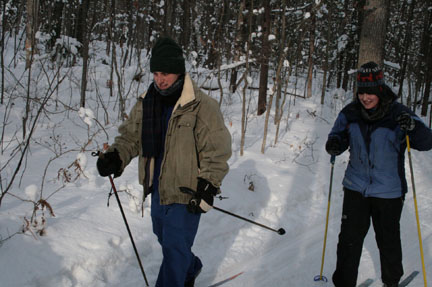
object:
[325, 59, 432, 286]
woman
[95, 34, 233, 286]
man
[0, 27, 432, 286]
ground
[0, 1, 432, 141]
trees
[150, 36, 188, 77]
hat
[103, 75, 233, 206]
jacket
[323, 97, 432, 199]
jacket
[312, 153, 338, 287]
ski stick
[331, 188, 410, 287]
pants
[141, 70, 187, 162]
scarf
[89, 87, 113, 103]
snow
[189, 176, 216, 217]
glove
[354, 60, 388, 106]
hat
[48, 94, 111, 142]
branch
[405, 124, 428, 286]
ski pole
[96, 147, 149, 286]
ski pole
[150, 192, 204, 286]
jeans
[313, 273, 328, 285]
bottom